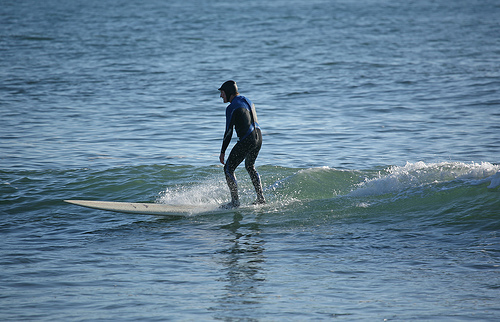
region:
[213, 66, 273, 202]
A black wet suit on a man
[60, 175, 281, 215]
A white surf board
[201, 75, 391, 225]
A man riding a wave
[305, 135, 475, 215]
A wave coming to shore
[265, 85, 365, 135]
Light shining on water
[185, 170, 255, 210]
Water spray around a man's feet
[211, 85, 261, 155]
Blue stripes on a black wet suit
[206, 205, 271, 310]
A man's reflection in the water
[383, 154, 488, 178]
The white top of a wave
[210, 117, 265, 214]
A man's knee bent while riding a surf board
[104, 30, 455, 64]
Picture taken outside.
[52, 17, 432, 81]
Picture taken during the day.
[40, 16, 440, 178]
It is a sunny day.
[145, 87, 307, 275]
A man is on a surfboard.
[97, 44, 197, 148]
The water is the ocean.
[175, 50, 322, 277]
The man is wearing a body suit.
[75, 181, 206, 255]
The surf board is white.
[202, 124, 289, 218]
The man's legs are apart.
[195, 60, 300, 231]
The body suit is blue and black.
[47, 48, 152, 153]
The water is dark blue and green.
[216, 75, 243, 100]
Man wearing a hat on the ocean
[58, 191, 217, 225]
Tip of a white surf board in the ocean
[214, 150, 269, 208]
Legs in a black wet suit on a surfboard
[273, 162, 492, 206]
Small wave on the ocean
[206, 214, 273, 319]
Reflection of a man on a surf board in the ocean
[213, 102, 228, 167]
Left arm of a man in a wet suit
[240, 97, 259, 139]
Zipped up zipper of a wet suit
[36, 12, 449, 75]
Calm ocean water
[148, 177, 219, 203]
White water from an ocean wave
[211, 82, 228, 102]
Face of a man facing left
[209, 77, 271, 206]
a man on the surfboard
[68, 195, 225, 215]
the white surfboard the man is riding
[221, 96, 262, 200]
the wetsuit the man is wearing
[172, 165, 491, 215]
the wave the man is riding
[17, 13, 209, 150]
some of the ocean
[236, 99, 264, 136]
the blue stripes on the back of the wetsuit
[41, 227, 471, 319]
some more of the ocean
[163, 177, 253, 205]
the splashing water of the wave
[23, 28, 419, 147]
the water of the ocean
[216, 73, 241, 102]
the man's head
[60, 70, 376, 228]
A surfer riding a white surfboard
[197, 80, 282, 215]
A surfer in a full-body wetsuit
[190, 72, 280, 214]
A surfer in a blue and black wetsuit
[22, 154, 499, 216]
A low wave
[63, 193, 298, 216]
A white surfboard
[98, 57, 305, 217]
A surfer riding a low wave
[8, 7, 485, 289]
The ocean with gentle waves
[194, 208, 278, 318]
The man's reflection in the water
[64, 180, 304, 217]
A surfboard cutting through the water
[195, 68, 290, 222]
A male surfer on the water